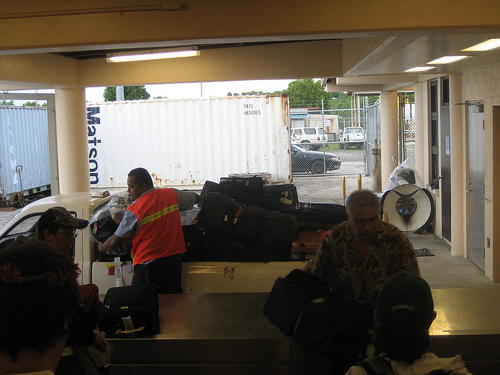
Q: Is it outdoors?
A: Yes, it is outdoors.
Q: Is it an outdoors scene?
A: Yes, it is outdoors.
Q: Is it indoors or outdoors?
A: It is outdoors.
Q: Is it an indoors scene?
A: No, it is outdoors.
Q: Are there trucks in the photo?
A: Yes, there is a truck.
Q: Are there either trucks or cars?
A: Yes, there is a truck.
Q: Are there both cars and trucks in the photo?
A: Yes, there are both a truck and a car.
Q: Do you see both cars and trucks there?
A: Yes, there are both a truck and a car.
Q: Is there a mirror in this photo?
A: No, there are no mirrors.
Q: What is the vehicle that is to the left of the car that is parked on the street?
A: The vehicle is a truck.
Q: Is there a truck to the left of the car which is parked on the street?
A: Yes, there is a truck to the left of the car.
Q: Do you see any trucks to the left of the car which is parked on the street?
A: Yes, there is a truck to the left of the car.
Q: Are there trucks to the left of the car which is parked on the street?
A: Yes, there is a truck to the left of the car.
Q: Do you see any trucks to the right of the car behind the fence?
A: No, the truck is to the left of the car.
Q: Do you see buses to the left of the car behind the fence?
A: No, there is a truck to the left of the car.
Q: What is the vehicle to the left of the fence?
A: The vehicle is a truck.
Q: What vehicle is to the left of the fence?
A: The vehicle is a truck.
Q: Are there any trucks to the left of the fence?
A: Yes, there is a truck to the left of the fence.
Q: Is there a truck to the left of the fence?
A: Yes, there is a truck to the left of the fence.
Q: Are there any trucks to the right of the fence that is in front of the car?
A: No, the truck is to the left of the fence.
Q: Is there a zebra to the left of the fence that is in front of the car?
A: No, there is a truck to the left of the fence.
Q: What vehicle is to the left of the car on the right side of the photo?
A: The vehicle is a truck.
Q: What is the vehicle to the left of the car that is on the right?
A: The vehicle is a truck.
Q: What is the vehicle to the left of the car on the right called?
A: The vehicle is a truck.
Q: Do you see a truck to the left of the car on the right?
A: Yes, there is a truck to the left of the car.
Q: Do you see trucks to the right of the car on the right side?
A: No, the truck is to the left of the car.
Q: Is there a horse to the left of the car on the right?
A: No, there is a truck to the left of the car.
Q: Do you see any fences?
A: Yes, there is a fence.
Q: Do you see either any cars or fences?
A: Yes, there is a fence.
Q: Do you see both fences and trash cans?
A: No, there is a fence but no trash cans.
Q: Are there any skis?
A: No, there are no skis.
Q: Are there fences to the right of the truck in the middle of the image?
A: Yes, there is a fence to the right of the truck.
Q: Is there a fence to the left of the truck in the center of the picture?
A: No, the fence is to the right of the truck.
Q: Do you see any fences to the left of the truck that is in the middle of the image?
A: No, the fence is to the right of the truck.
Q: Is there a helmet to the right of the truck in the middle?
A: No, there is a fence to the right of the truck.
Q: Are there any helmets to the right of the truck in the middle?
A: No, there is a fence to the right of the truck.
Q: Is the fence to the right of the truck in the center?
A: Yes, the fence is to the right of the truck.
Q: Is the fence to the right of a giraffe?
A: No, the fence is to the right of the truck.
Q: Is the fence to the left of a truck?
A: No, the fence is to the right of a truck.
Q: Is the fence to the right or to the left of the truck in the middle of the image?
A: The fence is to the right of the truck.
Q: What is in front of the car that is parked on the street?
A: The fence is in front of the car.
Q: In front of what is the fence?
A: The fence is in front of the car.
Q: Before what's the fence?
A: The fence is in front of the car.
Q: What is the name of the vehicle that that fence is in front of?
A: The vehicle is a car.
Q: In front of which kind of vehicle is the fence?
A: The fence is in front of the car.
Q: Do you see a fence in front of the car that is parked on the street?
A: Yes, there is a fence in front of the car.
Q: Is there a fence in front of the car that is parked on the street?
A: Yes, there is a fence in front of the car.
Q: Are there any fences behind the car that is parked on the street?
A: No, the fence is in front of the car.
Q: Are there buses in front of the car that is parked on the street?
A: No, there is a fence in front of the car.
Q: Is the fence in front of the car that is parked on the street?
A: Yes, the fence is in front of the car.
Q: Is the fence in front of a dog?
A: No, the fence is in front of the car.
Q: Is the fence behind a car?
A: No, the fence is in front of a car.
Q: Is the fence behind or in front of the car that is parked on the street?
A: The fence is in front of the car.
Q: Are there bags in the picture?
A: Yes, there is a bag.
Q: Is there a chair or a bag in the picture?
A: Yes, there is a bag.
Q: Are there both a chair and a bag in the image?
A: No, there is a bag but no chairs.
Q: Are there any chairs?
A: No, there are no chairs.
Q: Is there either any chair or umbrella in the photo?
A: No, there are no chairs or umbrellas.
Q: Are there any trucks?
A: Yes, there is a truck.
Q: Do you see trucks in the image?
A: Yes, there is a truck.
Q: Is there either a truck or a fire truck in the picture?
A: Yes, there is a truck.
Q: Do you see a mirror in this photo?
A: No, there are no mirrors.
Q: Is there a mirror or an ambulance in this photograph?
A: No, there are no mirrors or ambulances.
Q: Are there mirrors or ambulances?
A: No, there are no mirrors or ambulances.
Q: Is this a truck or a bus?
A: This is a truck.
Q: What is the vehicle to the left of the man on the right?
A: The vehicle is a truck.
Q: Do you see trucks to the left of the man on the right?
A: Yes, there is a truck to the left of the man.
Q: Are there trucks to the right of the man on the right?
A: No, the truck is to the left of the man.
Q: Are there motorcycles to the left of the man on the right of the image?
A: No, there is a truck to the left of the man.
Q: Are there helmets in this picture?
A: No, there are no helmets.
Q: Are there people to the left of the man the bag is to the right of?
A: Yes, there is a person to the left of the man.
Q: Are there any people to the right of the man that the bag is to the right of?
A: No, the person is to the left of the man.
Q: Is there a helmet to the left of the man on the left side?
A: No, there is a person to the left of the man.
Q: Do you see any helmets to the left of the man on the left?
A: No, there is a person to the left of the man.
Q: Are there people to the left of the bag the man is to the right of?
A: Yes, there is a person to the left of the bag.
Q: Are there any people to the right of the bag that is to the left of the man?
A: No, the person is to the left of the bag.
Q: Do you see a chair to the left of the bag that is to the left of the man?
A: No, there is a person to the left of the bag.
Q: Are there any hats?
A: Yes, there is a hat.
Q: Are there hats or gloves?
A: Yes, there is a hat.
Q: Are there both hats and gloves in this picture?
A: No, there is a hat but no gloves.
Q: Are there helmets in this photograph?
A: No, there are no helmets.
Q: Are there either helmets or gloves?
A: No, there are no helmets or gloves.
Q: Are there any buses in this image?
A: No, there are no buses.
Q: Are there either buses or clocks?
A: No, there are no buses or clocks.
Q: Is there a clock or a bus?
A: No, there are no buses or clocks.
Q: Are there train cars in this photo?
A: No, there are no train cars.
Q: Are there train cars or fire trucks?
A: No, there are no train cars or fire trucks.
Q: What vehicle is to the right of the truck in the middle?
A: The vehicle is a car.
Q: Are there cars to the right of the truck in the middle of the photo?
A: Yes, there is a car to the right of the truck.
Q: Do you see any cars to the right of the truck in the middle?
A: Yes, there is a car to the right of the truck.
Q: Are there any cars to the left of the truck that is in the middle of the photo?
A: No, the car is to the right of the truck.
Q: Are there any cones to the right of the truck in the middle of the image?
A: No, there is a car to the right of the truck.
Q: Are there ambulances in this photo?
A: No, there are no ambulances.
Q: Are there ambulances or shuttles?
A: No, there are no ambulances or shuttles.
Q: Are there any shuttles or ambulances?
A: No, there are no ambulances or shuttles.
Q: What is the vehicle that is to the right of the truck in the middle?
A: The vehicle is a car.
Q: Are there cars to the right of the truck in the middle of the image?
A: Yes, there is a car to the right of the truck.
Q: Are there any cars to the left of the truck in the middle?
A: No, the car is to the right of the truck.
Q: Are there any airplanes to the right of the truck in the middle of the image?
A: No, there is a car to the right of the truck.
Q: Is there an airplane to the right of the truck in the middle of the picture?
A: No, there is a car to the right of the truck.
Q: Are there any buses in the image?
A: No, there are no buses.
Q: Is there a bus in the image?
A: No, there are no buses.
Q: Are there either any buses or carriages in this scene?
A: No, there are no buses or carriages.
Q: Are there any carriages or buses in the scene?
A: No, there are no buses or carriages.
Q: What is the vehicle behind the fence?
A: The vehicle is a car.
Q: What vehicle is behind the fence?
A: The vehicle is a car.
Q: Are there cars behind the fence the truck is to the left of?
A: Yes, there is a car behind the fence.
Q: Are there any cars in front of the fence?
A: No, the car is behind the fence.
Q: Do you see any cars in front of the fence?
A: No, the car is behind the fence.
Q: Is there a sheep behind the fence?
A: No, there is a car behind the fence.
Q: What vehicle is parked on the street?
A: The vehicle is a car.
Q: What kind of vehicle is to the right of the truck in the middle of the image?
A: The vehicle is a car.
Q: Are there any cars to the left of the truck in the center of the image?
A: No, the car is to the right of the truck.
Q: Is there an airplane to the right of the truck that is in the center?
A: No, there is a car to the right of the truck.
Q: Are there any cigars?
A: No, there are no cigars.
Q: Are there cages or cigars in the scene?
A: No, there are no cigars or cages.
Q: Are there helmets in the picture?
A: No, there are no helmets.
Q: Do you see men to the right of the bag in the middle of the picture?
A: Yes, there is a man to the right of the bag.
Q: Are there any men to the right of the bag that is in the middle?
A: Yes, there is a man to the right of the bag.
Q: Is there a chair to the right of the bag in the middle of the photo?
A: No, there is a man to the right of the bag.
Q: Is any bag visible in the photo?
A: Yes, there is a bag.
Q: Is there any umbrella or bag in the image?
A: Yes, there is a bag.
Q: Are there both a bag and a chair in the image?
A: No, there is a bag but no chairs.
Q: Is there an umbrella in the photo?
A: No, there are no umbrellas.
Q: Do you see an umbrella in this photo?
A: No, there are no umbrellas.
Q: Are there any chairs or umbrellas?
A: No, there are no umbrellas or chairs.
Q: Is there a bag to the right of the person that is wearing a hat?
A: Yes, there is a bag to the right of the person.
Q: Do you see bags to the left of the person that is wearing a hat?
A: No, the bag is to the right of the person.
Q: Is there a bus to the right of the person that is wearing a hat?
A: No, there is a bag to the right of the person.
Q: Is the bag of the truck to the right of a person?
A: Yes, the bag is to the right of a person.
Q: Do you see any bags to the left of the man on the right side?
A: Yes, there is a bag to the left of the man.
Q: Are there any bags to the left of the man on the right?
A: Yes, there is a bag to the left of the man.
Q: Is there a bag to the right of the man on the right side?
A: No, the bag is to the left of the man.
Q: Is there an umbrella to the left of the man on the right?
A: No, there is a bag to the left of the man.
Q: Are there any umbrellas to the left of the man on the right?
A: No, there is a bag to the left of the man.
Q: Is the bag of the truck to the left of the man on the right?
A: Yes, the bag is to the left of the man.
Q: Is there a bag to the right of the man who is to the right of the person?
A: Yes, there is a bag to the right of the man.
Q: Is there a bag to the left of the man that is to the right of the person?
A: No, the bag is to the right of the man.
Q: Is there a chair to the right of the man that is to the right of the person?
A: No, there is a bag to the right of the man.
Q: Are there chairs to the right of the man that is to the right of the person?
A: No, there is a bag to the right of the man.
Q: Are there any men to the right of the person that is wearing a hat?
A: Yes, there is a man to the right of the person.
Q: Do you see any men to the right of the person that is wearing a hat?
A: Yes, there is a man to the right of the person.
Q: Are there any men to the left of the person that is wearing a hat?
A: No, the man is to the right of the person.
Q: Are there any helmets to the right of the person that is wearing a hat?
A: No, there is a man to the right of the person.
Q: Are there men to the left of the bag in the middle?
A: Yes, there is a man to the left of the bag.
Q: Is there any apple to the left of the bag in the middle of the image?
A: No, there is a man to the left of the bag.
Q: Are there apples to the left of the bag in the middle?
A: No, there is a man to the left of the bag.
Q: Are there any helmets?
A: No, there are no helmets.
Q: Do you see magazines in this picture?
A: No, there are no magazines.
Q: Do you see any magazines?
A: No, there are no magazines.